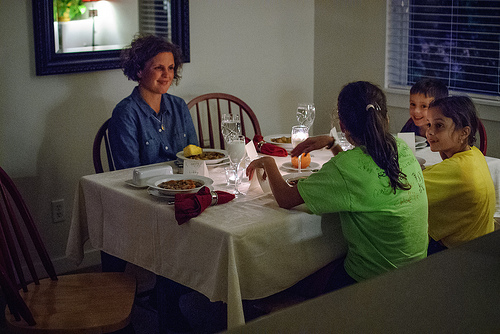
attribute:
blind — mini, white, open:
[387, 1, 498, 101]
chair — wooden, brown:
[0, 167, 141, 333]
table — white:
[62, 133, 499, 333]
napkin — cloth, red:
[173, 185, 235, 224]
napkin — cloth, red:
[241, 132, 288, 159]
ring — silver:
[209, 188, 218, 205]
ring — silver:
[255, 139, 266, 153]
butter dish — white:
[122, 163, 172, 188]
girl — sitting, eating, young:
[246, 80, 430, 295]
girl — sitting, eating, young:
[420, 95, 497, 256]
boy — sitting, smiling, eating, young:
[398, 77, 450, 148]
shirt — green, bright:
[297, 139, 429, 283]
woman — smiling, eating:
[106, 32, 200, 169]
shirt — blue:
[110, 84, 200, 168]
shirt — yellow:
[422, 147, 496, 248]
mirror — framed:
[49, 0, 172, 56]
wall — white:
[0, 0, 316, 273]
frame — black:
[30, 1, 193, 80]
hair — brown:
[336, 79, 411, 191]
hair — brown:
[427, 93, 479, 146]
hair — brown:
[408, 77, 451, 99]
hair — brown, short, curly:
[117, 34, 183, 86]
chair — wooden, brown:
[92, 117, 118, 174]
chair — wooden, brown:
[185, 92, 263, 148]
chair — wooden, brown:
[401, 112, 490, 157]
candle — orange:
[291, 151, 311, 168]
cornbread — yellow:
[181, 144, 201, 157]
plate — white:
[174, 147, 231, 163]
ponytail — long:
[362, 106, 410, 193]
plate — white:
[145, 173, 214, 198]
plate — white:
[265, 132, 301, 151]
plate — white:
[282, 171, 317, 190]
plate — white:
[411, 131, 427, 150]